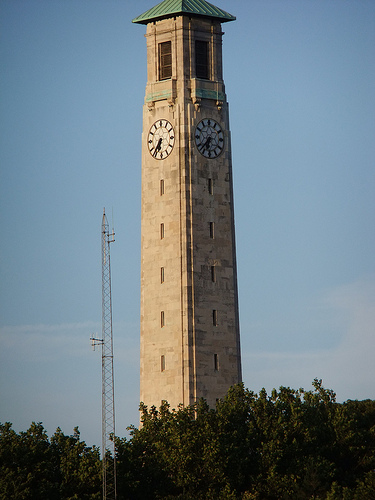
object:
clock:
[194, 118, 226, 159]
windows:
[208, 175, 214, 195]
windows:
[210, 262, 216, 283]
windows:
[210, 307, 217, 328]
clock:
[148, 118, 175, 160]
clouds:
[2, 330, 136, 369]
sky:
[259, 106, 280, 122]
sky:
[260, 17, 371, 166]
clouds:
[253, 345, 373, 374]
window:
[160, 179, 164, 195]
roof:
[131, 0, 237, 23]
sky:
[252, 165, 306, 276]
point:
[103, 206, 107, 210]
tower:
[89, 206, 118, 500]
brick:
[191, 197, 207, 207]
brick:
[198, 262, 212, 273]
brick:
[216, 198, 229, 207]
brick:
[183, 246, 193, 256]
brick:
[184, 262, 194, 270]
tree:
[108, 376, 374, 499]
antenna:
[109, 204, 115, 243]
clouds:
[7, 327, 78, 350]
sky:
[307, 186, 370, 264]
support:
[90, 333, 102, 351]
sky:
[19, 54, 95, 285]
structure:
[132, 0, 242, 428]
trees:
[2, 376, 102, 493]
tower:
[131, 0, 242, 421]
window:
[193, 36, 214, 79]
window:
[159, 40, 174, 80]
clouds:
[242, 297, 373, 338]